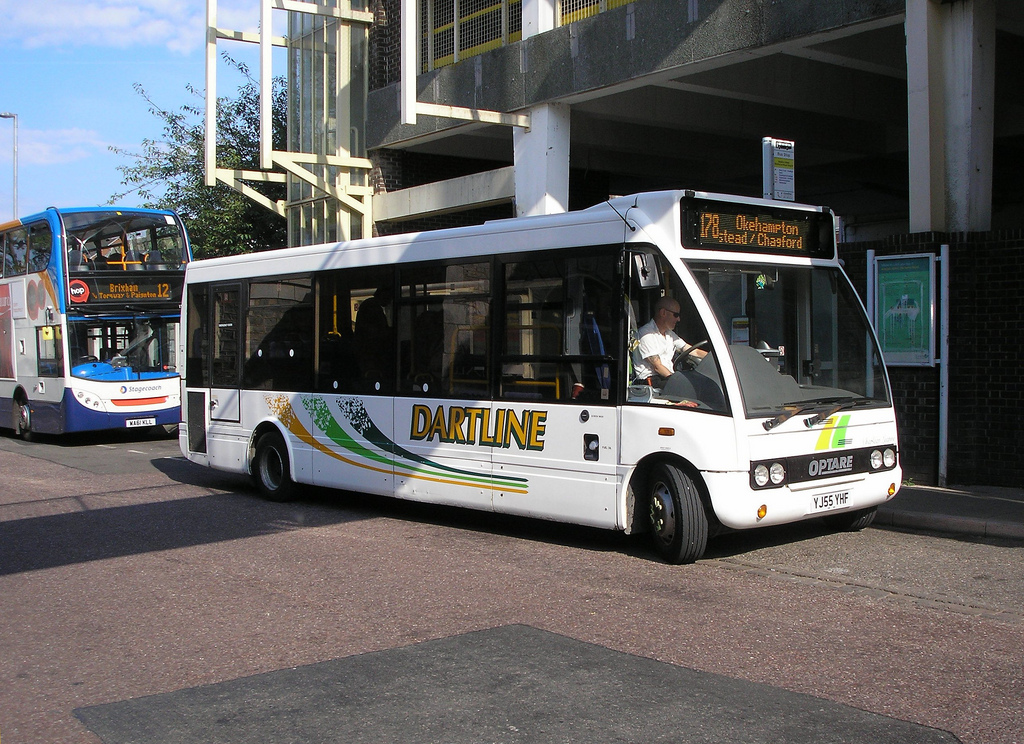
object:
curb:
[875, 485, 1023, 548]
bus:
[174, 189, 902, 567]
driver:
[633, 294, 710, 377]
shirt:
[632, 319, 687, 380]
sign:
[877, 257, 930, 362]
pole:
[864, 249, 875, 398]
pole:
[938, 241, 948, 485]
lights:
[700, 214, 802, 249]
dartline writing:
[410, 404, 548, 451]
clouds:
[3, 126, 192, 168]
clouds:
[0, 0, 286, 57]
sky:
[0, 0, 287, 224]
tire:
[635, 454, 709, 565]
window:
[183, 243, 622, 406]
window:
[681, 243, 892, 421]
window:
[624, 243, 734, 422]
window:
[499, 254, 618, 402]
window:
[210, 283, 243, 384]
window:
[35, 324, 64, 378]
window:
[243, 272, 315, 391]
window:
[309, 254, 415, 394]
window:
[401, 262, 490, 401]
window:
[62, 203, 189, 272]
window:
[57, 308, 192, 377]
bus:
[0, 206, 192, 440]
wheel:
[251, 430, 290, 504]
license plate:
[812, 490, 848, 509]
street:
[0, 436, 1023, 743]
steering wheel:
[672, 332, 710, 375]